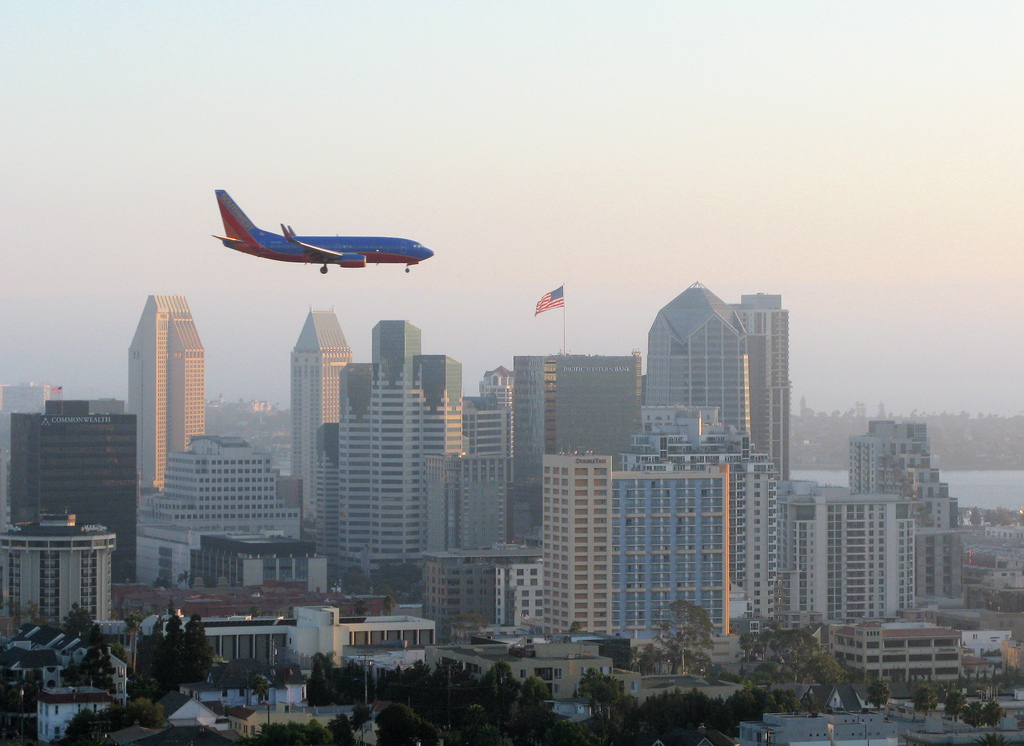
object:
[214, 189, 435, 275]
plane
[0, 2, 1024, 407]
sky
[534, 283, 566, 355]
flag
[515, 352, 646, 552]
building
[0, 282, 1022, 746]
buildings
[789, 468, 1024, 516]
water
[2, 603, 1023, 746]
trees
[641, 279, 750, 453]
building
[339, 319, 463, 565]
building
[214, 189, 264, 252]
tail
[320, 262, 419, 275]
gear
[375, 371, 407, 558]
windows